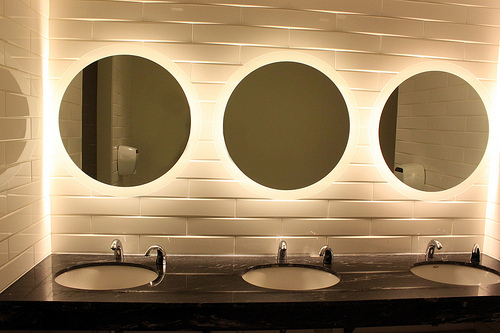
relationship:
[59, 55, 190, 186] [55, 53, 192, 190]
reflection in mirror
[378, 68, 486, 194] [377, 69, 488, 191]
reflection in mirror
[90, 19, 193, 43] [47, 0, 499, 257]
brick on wall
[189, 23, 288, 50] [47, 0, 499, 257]
brick on wall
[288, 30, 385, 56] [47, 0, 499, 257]
brick on wall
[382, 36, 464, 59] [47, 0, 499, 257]
brick on wall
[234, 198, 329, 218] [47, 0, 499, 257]
brick on wall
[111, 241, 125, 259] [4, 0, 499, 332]
faucet in bathroom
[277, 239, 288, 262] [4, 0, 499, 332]
faucet in bathroom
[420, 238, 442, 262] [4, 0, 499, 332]
faucet in bathroom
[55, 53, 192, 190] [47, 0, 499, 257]
mirror on wall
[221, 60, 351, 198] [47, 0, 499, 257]
mirror on wall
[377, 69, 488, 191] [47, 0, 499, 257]
mirror on wall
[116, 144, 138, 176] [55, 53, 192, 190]
hand dryer in mirror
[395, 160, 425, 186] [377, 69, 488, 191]
hand dryer in mirror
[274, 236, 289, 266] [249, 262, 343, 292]
tap for sink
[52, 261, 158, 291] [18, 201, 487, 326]
sink on counter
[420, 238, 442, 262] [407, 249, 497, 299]
faucet belonging to third sink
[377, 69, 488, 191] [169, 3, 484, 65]
mirror on wall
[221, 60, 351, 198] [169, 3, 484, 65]
mirror on wall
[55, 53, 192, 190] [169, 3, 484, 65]
mirror on wall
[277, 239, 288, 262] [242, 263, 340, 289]
faucet on sink